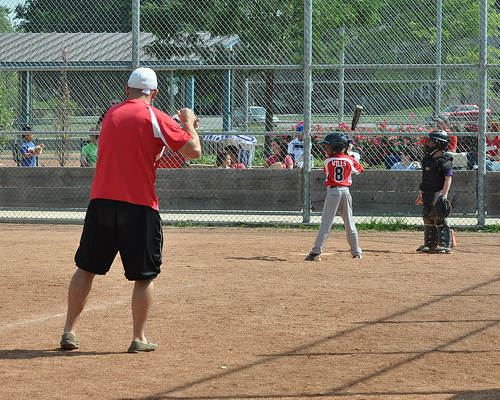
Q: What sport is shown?
A: Baseball.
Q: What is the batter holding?
A: Baseball bat.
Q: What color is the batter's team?
A: Red.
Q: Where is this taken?
A: Ball park.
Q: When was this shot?
A: Daytime.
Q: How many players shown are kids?
A: 2.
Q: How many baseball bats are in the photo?
A: 1.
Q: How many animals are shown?
A: 0.